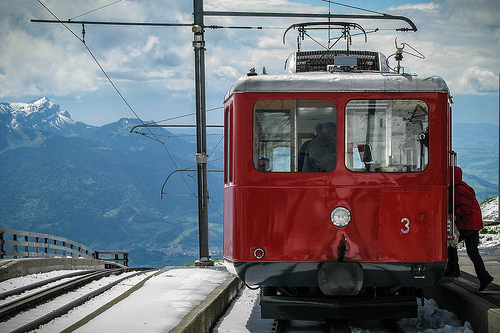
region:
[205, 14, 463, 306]
A red train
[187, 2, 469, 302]
The train is on a moutain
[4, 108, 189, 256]
Green lush mountainside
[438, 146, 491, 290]
Person boarding the train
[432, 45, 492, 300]
The person's jacket matches the train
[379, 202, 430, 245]
Number 3 on the front of the train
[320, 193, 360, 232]
One headlight on the train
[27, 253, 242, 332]
Snow on the train tracks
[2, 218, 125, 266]
A guard rail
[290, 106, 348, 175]
Other people are on the train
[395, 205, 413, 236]
number 3 on front of train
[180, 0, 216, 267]
a black pole on sidewalk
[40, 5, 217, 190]
power lines on a pole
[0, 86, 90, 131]
white snow on top a mountain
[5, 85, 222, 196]
mountain on the background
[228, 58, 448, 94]
ceiling of train is gray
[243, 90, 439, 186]
two windows on front a train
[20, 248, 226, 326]
snow on the sidewalk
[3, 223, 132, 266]
a rail of wood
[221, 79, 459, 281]
red front of train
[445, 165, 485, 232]
red coat of person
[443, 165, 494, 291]
person entering into train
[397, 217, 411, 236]
number on the train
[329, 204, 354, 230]
light on front of train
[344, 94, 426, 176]
window on front of train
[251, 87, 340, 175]
window on front of train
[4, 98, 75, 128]
snow capped mountains in backgroun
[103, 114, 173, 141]
mountain in the background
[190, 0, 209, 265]
large pole by train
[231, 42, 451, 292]
red light rail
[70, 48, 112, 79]
white clouds in blue sky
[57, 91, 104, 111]
white clouds in blue sky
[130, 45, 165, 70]
white clouds in blue sky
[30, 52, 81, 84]
white clouds in blue sky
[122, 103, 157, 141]
white clouds in blue sky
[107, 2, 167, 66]
white clouds in blue sky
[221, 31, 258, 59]
white clouds in blue sky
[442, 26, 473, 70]
white clouds in blue sky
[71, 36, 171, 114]
white clouds in blue sky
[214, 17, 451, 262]
red travel train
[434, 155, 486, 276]
child boarding a train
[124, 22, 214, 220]
lines powering travel train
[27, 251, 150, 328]
railroad tracks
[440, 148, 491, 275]
child in red shirt boarding train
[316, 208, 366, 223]
light on front of red train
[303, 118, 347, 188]
passenger waiting to sit on train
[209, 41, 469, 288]
red trolley passenger train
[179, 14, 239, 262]
power line powering train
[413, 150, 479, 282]
red shirted child boarding travel train